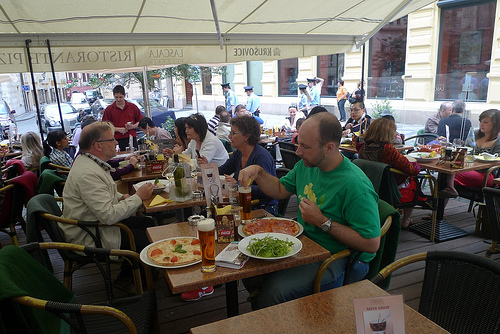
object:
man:
[102, 85, 142, 151]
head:
[295, 112, 343, 169]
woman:
[217, 114, 280, 217]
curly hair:
[229, 117, 262, 145]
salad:
[246, 235, 297, 257]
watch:
[321, 219, 335, 233]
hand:
[299, 197, 326, 225]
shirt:
[58, 150, 142, 260]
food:
[148, 178, 164, 187]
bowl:
[137, 179, 169, 193]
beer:
[239, 185, 251, 221]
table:
[0, 0, 500, 334]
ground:
[386, 189, 494, 306]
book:
[214, 239, 254, 270]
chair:
[366, 249, 498, 332]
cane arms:
[366, 251, 430, 286]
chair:
[309, 193, 397, 296]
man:
[239, 110, 382, 310]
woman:
[173, 113, 231, 168]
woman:
[361, 116, 418, 225]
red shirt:
[357, 142, 421, 180]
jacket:
[57, 155, 141, 262]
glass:
[198, 217, 217, 272]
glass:
[238, 185, 252, 223]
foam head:
[196, 220, 214, 231]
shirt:
[102, 100, 144, 139]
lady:
[334, 80, 352, 121]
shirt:
[336, 87, 350, 102]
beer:
[197, 217, 218, 274]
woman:
[42, 130, 78, 179]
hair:
[43, 128, 69, 158]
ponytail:
[40, 137, 51, 157]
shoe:
[182, 287, 215, 301]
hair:
[364, 117, 397, 142]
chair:
[0, 237, 158, 334]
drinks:
[238, 185, 253, 220]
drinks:
[194, 217, 220, 271]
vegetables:
[246, 234, 295, 258]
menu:
[214, 239, 253, 269]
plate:
[237, 232, 302, 260]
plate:
[139, 237, 209, 270]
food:
[244, 219, 300, 237]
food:
[247, 234, 295, 257]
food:
[147, 237, 198, 266]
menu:
[353, 292, 406, 333]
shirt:
[281, 153, 380, 264]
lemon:
[246, 177, 254, 188]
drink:
[237, 185, 254, 222]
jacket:
[0, 243, 81, 334]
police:
[220, 78, 322, 123]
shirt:
[279, 155, 384, 263]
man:
[58, 120, 159, 292]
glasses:
[97, 137, 116, 142]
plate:
[238, 217, 304, 240]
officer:
[220, 83, 238, 110]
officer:
[242, 86, 261, 116]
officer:
[296, 84, 309, 112]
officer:
[305, 77, 323, 107]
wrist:
[319, 216, 333, 233]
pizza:
[242, 218, 300, 237]